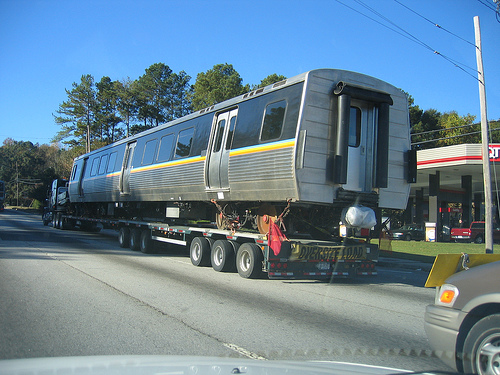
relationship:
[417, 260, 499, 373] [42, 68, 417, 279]
car behind car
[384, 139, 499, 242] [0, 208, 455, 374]
gas station behind road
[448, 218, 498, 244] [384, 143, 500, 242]
red truck at gas station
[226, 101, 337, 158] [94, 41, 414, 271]
window on train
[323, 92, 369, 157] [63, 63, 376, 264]
window on train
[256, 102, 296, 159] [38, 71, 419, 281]
window on train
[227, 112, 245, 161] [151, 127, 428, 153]
window on train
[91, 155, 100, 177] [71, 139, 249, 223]
window on train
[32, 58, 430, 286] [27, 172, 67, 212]
car on truck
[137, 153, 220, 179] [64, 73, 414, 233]
stripe on train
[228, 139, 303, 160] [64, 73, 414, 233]
stripe on train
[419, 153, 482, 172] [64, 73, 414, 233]
stripe on train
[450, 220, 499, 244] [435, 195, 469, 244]
red truck getting gas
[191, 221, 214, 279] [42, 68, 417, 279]
wheel on car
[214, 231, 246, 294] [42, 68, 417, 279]
wheel on car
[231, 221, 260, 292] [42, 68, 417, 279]
wheel on car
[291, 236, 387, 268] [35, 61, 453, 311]
sign on truck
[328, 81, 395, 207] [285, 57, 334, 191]
door on back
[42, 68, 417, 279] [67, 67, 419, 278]
car carrying trailer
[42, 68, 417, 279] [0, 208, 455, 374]
car on road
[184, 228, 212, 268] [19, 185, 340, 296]
wheel of a truck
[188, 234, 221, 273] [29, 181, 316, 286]
wheel of a truck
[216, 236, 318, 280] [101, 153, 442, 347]
wheel of a truck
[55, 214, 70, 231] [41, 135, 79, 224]
wheel of a truck